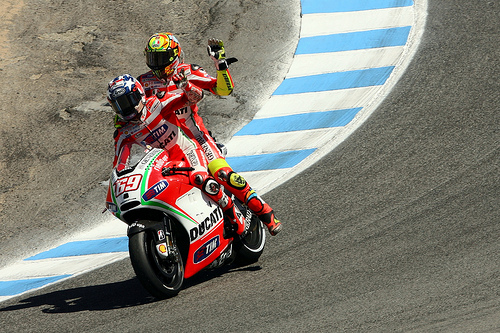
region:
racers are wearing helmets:
[96, 33, 204, 160]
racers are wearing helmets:
[81, 11, 187, 124]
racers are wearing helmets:
[94, 19, 202, 128]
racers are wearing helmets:
[76, 12, 208, 136]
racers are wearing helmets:
[84, 29, 211, 137]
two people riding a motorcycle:
[64, 32, 284, 303]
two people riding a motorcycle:
[77, 26, 277, 311]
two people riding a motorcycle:
[76, 39, 266, 289]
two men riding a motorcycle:
[76, 26, 311, 300]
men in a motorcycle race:
[9, 4, 482, 332]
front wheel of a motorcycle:
[117, 205, 192, 297]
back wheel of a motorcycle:
[226, 198, 273, 272]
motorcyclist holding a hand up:
[133, 16, 261, 123]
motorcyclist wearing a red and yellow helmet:
[131, 11, 243, 111]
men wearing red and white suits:
[95, 14, 287, 254]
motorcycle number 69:
[106, 160, 148, 204]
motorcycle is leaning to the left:
[86, 20, 310, 311]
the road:
[356, 220, 419, 289]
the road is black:
[406, 156, 488, 228]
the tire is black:
[126, 232, 183, 292]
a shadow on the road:
[75, 273, 139, 311]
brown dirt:
[31, 134, 76, 196]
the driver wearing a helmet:
[111, 75, 150, 122]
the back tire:
[238, 238, 270, 263]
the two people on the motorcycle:
[103, 32, 280, 297]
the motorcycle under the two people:
[101, 30, 282, 291]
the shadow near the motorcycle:
[0, 146, 266, 310]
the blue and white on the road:
[0, 0, 499, 330]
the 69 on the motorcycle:
[103, 147, 266, 297]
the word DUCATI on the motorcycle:
[102, 143, 266, 294]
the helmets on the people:
[104, 33, 281, 237]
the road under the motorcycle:
[0, 0, 498, 330]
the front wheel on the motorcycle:
[102, 140, 266, 295]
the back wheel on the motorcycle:
[101, 137, 266, 295]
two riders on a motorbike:
[95, 23, 284, 280]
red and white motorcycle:
[110, 142, 265, 297]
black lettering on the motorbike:
[185, 213, 222, 242]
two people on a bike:
[31, 16, 269, 291]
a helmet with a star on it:
[107, 72, 152, 117]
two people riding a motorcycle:
[100, 24, 285, 246]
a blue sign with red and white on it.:
[141, 177, 170, 203]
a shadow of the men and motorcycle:
[2, 274, 178, 317]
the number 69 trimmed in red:
[111, 174, 143, 195]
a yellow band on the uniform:
[203, 152, 233, 178]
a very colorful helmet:
[141, 26, 184, 79]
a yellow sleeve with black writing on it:
[212, 68, 237, 100]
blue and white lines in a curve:
[0, 2, 431, 302]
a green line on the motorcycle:
[136, 148, 199, 231]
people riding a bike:
[71, 28, 282, 255]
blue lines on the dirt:
[243, 159, 297, 173]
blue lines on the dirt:
[46, 233, 165, 268]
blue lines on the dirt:
[3, 273, 53, 302]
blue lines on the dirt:
[258, 71, 399, 106]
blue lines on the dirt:
[281, 34, 428, 56]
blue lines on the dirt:
[302, 0, 451, 20]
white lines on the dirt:
[225, 126, 346, 161]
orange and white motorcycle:
[100, 138, 267, 303]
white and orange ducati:
[96, 141, 276, 296]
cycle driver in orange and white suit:
[101, 68, 249, 248]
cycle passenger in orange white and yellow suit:
[132, 23, 281, 234]